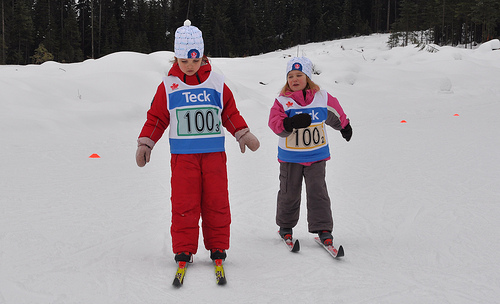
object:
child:
[134, 19, 261, 262]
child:
[267, 56, 353, 246]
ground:
[1, 29, 499, 304]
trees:
[1, 1, 48, 66]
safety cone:
[88, 152, 101, 159]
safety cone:
[399, 119, 407, 124]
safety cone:
[453, 113, 460, 117]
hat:
[173, 19, 204, 60]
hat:
[286, 55, 315, 81]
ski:
[172, 261, 186, 286]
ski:
[213, 259, 226, 285]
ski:
[277, 230, 301, 254]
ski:
[312, 236, 345, 260]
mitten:
[282, 113, 311, 132]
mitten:
[340, 124, 353, 141]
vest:
[162, 70, 226, 155]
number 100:
[184, 109, 216, 133]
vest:
[275, 89, 330, 163]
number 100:
[292, 127, 319, 146]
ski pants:
[273, 160, 333, 233]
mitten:
[135, 137, 155, 167]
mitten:
[234, 128, 260, 154]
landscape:
[0, 1, 499, 303]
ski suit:
[137, 55, 249, 254]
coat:
[266, 86, 349, 166]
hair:
[277, 74, 320, 97]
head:
[286, 58, 313, 92]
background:
[0, 0, 499, 65]